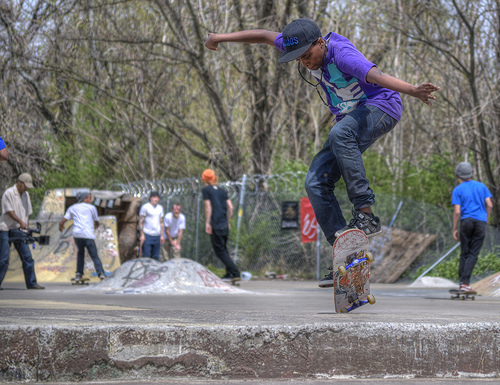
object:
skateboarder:
[206, 18, 435, 288]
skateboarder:
[449, 159, 494, 288]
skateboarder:
[200, 168, 235, 279]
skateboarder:
[135, 190, 164, 262]